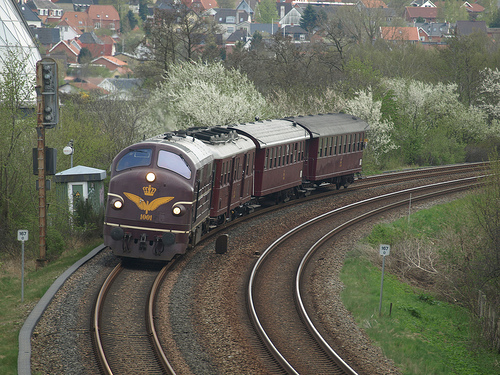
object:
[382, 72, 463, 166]
tree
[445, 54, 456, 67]
leaf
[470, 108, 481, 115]
leaf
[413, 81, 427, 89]
leaf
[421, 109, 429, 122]
leaf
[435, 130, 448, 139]
leaf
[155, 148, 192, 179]
window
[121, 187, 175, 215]
golden bird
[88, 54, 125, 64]
roof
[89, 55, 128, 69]
house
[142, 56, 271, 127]
tree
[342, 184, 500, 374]
grass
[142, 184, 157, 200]
crown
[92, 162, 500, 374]
tracks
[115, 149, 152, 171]
window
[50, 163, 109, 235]
building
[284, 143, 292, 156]
window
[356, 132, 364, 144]
window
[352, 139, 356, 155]
window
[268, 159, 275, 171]
window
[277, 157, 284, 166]
window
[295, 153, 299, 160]
window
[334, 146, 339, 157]
window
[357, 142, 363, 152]
window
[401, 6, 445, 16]
rooftop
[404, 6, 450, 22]
house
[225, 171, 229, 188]
window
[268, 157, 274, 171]
window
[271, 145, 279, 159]
window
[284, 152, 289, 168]
window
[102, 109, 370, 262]
train car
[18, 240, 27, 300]
pole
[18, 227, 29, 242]
sign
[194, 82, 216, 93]
blossoms